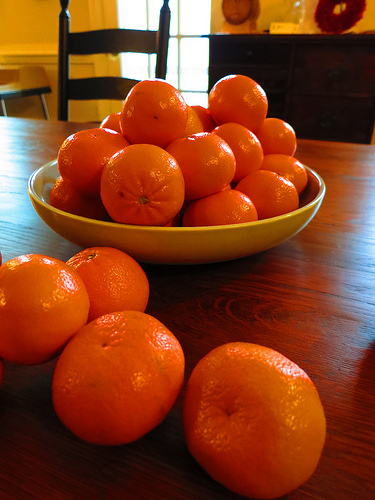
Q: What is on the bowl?
A: Oranges.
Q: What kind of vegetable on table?
A: It's not vegetable it's fruit.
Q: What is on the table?
A: Oranges.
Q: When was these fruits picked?
A: It's hard to tell.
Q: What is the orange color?
A: Orange.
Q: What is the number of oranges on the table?
A: Four.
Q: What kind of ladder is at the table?
A: Black ladder.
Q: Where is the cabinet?
A: Against the wall.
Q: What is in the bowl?
A: Navel oranges.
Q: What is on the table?
A: Oranges.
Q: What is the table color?
A: Brown.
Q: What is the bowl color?
A: Yellow.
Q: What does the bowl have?
A: Oranges.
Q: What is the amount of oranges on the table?
A: Four oranges.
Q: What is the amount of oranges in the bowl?
A: Fourteen.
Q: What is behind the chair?
A: A window.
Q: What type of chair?
A: Wooden.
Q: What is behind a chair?
A: Window.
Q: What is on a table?
A: Orange.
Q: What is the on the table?
A: Oranges.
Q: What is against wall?
A: Drawers.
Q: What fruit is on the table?
A: Oranges.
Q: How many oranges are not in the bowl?
A: 4.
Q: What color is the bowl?
A: Yellow.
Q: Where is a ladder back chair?
A: At the top left.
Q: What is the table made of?
A: Wood.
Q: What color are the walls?
A: Yellow.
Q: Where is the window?
A: Behind the chair.